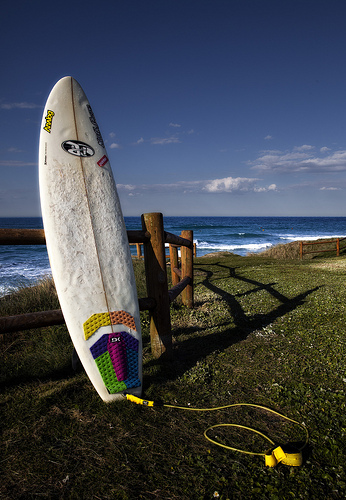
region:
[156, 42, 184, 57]
dark blue sky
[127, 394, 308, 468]
yellow foot strap connected to surfboard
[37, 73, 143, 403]
surfboard leaning against a wooden fence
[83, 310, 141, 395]
multi-colored padding on back of surfboard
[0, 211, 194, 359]
wooden fence on surrounding the beach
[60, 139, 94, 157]
black and white pattern on surfboard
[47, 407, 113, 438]
green grass that the surfboard is sitting on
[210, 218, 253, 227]
light blue water in the ocean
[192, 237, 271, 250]
whitecaps from the waves in the ocean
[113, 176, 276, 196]
white fluffy clouds in the sky above the water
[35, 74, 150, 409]
surf board leaning against fence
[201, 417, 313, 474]
yellow ankle strap on ground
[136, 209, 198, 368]
brown wooden fence post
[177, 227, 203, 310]
brown wooden fence post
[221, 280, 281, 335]
short green grass with white flowers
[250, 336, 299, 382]
short green grass with white flowers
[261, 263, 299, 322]
short green grass with white flowers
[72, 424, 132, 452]
short green grass with white flowers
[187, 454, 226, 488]
short green grass with white flowers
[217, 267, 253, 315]
short green grass with white flowers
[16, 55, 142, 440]
a surfboard standing up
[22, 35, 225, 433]
a surfboard leaning on a fence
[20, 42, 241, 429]
surfboard leaning on wood fence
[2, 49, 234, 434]
a white board standing up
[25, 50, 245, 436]
a white surfboard standing up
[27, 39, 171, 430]
a white board leaning on fence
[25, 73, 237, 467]
a white surfboard on a fence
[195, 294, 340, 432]
a field of grass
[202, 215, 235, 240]
a body of water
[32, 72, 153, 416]
surfboard leaning on fence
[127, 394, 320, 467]
yellow cord laying on ground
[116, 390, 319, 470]
yellow cord attached to surfboard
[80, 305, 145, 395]
colored patches on end of surfboard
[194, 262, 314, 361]
shadows of fence posts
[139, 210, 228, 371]
wooden fence posts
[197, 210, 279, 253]
ocean with waves breaking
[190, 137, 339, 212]
sky with white clouds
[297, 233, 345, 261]
wooden fence posts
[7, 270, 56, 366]
grass growing behind fence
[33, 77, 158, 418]
white wake board on fence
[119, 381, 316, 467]
yellow wake board safety rope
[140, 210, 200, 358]
brown wooden fence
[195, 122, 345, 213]
clear sky with white clouds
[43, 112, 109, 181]
several stickers on wake board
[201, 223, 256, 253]
blue water with small waves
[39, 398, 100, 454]
green grass with brown patches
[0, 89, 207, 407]
wake board sitting on fence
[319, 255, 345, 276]
brown sand surrounded by green grass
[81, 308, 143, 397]
foot padding on wake board